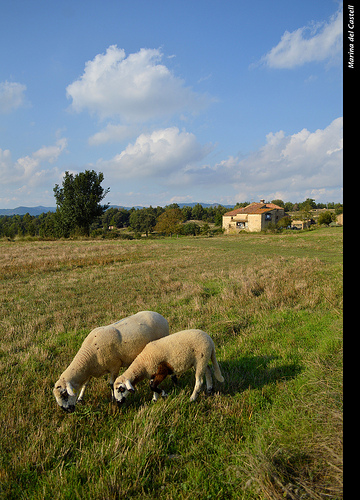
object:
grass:
[0, 225, 344, 499]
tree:
[53, 169, 111, 241]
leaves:
[62, 179, 65, 183]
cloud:
[66, 44, 217, 128]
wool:
[106, 315, 145, 335]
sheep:
[53, 306, 171, 410]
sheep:
[111, 328, 226, 406]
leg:
[150, 362, 162, 398]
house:
[221, 201, 287, 235]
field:
[0, 199, 342, 498]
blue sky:
[0, 1, 345, 212]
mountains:
[1, 201, 219, 215]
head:
[51, 377, 87, 413]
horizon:
[0, 188, 223, 217]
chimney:
[257, 197, 268, 206]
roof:
[223, 203, 283, 214]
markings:
[117, 386, 128, 395]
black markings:
[117, 385, 126, 394]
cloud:
[255, 10, 342, 70]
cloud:
[108, 127, 213, 179]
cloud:
[210, 117, 342, 195]